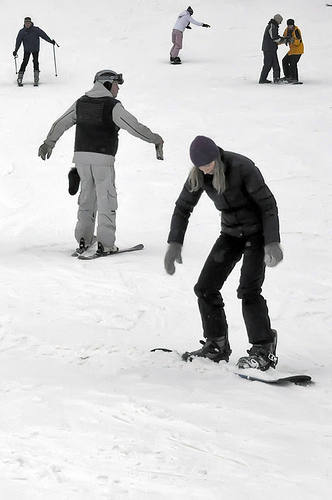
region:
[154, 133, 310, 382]
the person dressed in dark clothing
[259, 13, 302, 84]
two people holding each others hands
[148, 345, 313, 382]
the snow board under the person wearing dark clothing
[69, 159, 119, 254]
the gray pants on the man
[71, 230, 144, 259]
the skis under the person wearing gray pants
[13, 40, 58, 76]
the two ski poles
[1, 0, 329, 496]
the white snow on the ground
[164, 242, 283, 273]
the gray gloves on the person's hands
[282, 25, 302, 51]
the yellow-orange jacket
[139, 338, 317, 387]
the white snow around the snow board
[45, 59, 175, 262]
a man walking on his skis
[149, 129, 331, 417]
a woman snowboarding down the slope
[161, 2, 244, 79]
a snowboarder trying not to fall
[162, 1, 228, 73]
a snowboarder losing balance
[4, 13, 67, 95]
a man skiing down the slope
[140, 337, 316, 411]
a woman standing on her snow-covered snowboard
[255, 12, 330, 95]
two people attempting to snowboard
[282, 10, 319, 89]
a person learning to snowboard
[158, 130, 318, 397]
a tall woman snowboarding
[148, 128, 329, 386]
a tall and skinny woman on her snowboard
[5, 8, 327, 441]
people on the snow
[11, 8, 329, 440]
people skiing and snowboarding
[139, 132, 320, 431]
a woman snowboarding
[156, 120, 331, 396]
a woman with long hair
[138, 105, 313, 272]
a woman wearing a beanie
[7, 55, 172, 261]
a person on skies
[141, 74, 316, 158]
white snow on the ground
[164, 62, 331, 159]
white snow covering the ground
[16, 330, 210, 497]
snow covering the ground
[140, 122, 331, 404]
a woman balancing on her snowboard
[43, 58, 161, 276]
a guy trying to walk with skis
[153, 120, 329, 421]
a tall, thin woman on a snowboard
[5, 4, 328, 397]
people enjoying the slopes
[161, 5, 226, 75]
a person trying not to fall down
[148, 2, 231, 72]
a snowboarder trying to find balance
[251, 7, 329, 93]
a man teaching another person how to snowboard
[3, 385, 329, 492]
fresh white snow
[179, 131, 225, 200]
a woman wearing a purple beanie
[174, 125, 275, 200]
woman with long blond hair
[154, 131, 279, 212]
woman with black toboggan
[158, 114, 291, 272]
woman wearing a pair of gray gloves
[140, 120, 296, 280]
woman wearing black jacket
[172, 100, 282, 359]
woman wearing black pants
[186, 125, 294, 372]
woman wearing black boots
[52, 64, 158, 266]
man wearing black ear muffs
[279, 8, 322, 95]
woman wearing yellow jacket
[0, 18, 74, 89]
man holding pair of ski poles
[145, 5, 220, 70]
man wearing white hoodie